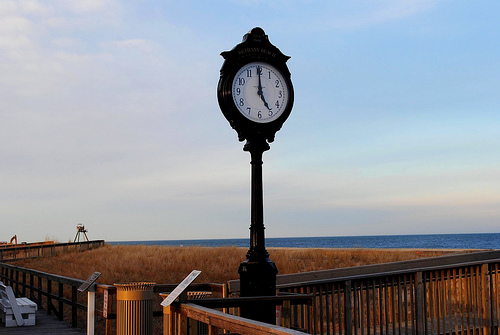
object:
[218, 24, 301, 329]
clock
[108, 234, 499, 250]
water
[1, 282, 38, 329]
chair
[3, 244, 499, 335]
fence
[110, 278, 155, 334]
trash can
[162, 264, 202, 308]
sign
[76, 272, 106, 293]
sign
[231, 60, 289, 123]
face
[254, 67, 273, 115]
hands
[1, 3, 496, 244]
sky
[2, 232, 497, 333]
ground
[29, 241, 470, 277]
grass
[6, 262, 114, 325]
guard rail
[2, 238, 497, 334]
board walk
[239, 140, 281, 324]
pole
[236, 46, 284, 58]
writing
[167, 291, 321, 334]
railing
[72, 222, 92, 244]
contraption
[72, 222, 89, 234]
top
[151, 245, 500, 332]
walkway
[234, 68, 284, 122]
numbers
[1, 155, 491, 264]
distance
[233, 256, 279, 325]
stand